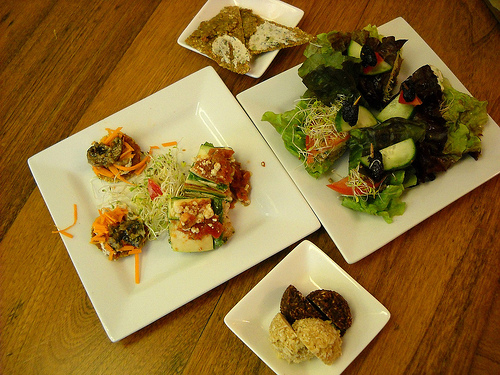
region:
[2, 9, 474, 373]
food on white plates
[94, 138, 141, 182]
small salad on plate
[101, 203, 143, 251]
small salad on plate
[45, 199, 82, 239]
orange slice of carrot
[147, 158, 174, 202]
green salad on plate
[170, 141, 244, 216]
red food on plate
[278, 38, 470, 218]
large salad on a plate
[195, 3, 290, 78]
slices of bread on plate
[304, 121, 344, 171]
red tomato on plate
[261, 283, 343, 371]
white and brown cookies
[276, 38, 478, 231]
salad on white plate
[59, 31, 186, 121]
wooden table top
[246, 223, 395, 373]
small square plate with brown bread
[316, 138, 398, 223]
tomato on salad on plate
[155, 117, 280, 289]
sandwich on square white plate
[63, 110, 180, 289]
carrots on plate with sandwich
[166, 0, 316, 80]
small plate with chips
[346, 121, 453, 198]
cucumber on plate with salad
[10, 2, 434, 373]
four square white plates on a table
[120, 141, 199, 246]
bean sprouts on plate with sandwich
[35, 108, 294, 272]
white and square plate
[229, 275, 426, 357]
small and white plate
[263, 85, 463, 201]
green salad on plate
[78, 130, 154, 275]
orange carrots on salad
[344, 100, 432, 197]
green cucumbers on salad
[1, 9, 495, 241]
plates on wooden table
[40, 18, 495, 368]
large and small plates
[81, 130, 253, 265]
small sandwiches on plate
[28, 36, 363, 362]
plate on a table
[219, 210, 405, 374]
plate on a table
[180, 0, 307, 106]
plate on a table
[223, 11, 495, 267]
plate on a table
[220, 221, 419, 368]
white plate on a plate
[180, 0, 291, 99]
white plate on a plate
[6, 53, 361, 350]
square plate on a table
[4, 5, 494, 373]
square white plates on table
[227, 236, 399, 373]
small white plate on table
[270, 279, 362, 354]
halves of cookies on plate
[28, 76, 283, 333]
large square plate on table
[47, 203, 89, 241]
orange carrot slice on plate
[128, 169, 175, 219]
green lettuce on plate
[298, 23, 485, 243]
large white plate on table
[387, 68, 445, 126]
small slice of sandwich on plate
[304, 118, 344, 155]
tomato on a plate